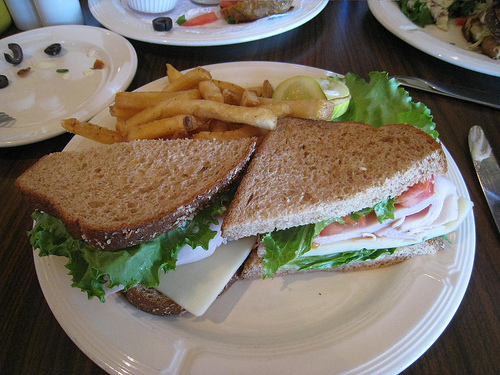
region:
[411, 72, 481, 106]
this is a knife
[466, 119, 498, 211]
the knife has some butter in it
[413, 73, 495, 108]
the knife is shinny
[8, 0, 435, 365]
the food is on the plate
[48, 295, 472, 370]
the plate is white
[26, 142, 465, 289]
this sandwich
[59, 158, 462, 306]
the sandwich has meat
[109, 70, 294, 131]
this is french fries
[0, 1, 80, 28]
these are cups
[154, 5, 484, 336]
the plates are on top of a table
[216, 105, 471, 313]
sandwich with lettuce and tomato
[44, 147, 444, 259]
sandwich with lettuce and tomato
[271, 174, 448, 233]
Tomatos on a sandwich.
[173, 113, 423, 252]
Pieces of wheat bread.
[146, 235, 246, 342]
White cheese on bread.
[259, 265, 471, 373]
White plate on table.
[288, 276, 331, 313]
Black speck on table.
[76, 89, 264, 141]
French fries crispy and golden.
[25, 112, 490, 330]
Two sandwiches on wheat bread.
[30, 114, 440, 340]
A sandwich cut in half.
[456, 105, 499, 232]
Silver butter knife with mayo on it.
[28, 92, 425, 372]
Sandwich and french fries.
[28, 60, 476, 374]
a round white plate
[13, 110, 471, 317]
a sandwich on the plate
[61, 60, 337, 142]
fries on the plate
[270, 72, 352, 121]
a pickle on the plate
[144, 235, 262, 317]
cheese on the sandwich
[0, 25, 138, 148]
a used plate on the table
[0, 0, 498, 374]
a wooden table with plates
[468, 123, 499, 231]
a dirty knife on the table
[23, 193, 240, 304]
a piece of lettuce on the sandwich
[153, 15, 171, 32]
a piece of an olive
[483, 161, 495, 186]
section of a knife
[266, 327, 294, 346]
section of a white plate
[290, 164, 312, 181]
section of a piece of bread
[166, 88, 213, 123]
part of french fries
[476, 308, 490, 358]
section of a brown table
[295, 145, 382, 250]
section of a sandwitch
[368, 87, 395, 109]
part of a green vegetable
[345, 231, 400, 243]
the inside part of a sandwitch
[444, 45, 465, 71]
edge of a white plate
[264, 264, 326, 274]
bottom part of a sandwitch